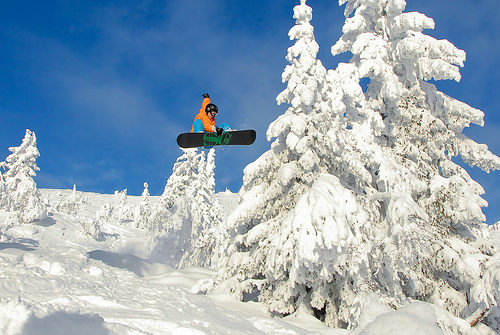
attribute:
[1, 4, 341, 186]
sky — blue 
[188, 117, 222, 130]
ski pant — turquoise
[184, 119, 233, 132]
pants — blue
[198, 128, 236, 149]
logo — green 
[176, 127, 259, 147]
snowboard — black, green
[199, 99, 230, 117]
helmet — black 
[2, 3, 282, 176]
sky — blue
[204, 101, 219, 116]
helmet — black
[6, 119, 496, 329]
mountain — snow covered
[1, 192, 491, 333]
ground — snowy, snow covered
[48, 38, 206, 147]
sky — dark blue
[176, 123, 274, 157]
snowboard — black, green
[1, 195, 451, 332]
hill — snowy, white, bright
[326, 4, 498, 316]
tree — snow covered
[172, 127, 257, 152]
snowboard — black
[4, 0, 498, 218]
sky — clear, dark blue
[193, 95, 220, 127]
top — orange